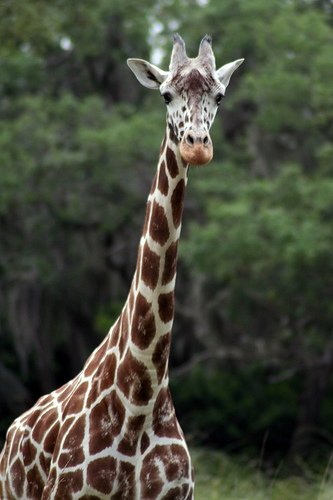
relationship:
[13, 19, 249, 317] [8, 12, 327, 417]
trees in background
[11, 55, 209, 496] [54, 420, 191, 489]
giraffe has spots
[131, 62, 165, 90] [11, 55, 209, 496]
ear of giraffe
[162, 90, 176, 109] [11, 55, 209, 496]
eye of giraffe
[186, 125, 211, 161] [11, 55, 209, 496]
nose of giraffe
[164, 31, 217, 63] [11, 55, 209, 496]
ossicones of giraffe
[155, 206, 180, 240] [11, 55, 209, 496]
fur of giraffe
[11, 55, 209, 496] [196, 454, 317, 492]
giraffe in grass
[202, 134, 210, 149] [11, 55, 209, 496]
nostril of giraffe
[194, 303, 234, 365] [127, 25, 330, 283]
bark of tree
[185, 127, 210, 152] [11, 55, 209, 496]
nose of giraffe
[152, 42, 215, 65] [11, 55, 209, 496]
horns of giraffe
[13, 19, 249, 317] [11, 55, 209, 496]
trees behind giraffe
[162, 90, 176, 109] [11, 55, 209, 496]
eye on giraffe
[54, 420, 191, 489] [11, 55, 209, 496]
spots on giraffe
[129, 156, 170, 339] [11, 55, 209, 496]
neck of giraffe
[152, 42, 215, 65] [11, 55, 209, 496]
horns on giraffe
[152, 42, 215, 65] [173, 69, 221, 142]
horns on head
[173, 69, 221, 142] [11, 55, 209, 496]
head of giraffe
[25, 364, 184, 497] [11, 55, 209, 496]
body of giraffe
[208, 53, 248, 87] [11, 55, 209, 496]
ear of giraffe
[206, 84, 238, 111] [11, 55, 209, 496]
eye of giraffe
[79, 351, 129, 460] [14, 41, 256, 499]
print of animal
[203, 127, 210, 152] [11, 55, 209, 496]
nostril of giraffe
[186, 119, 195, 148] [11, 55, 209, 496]
nostril of giraffe